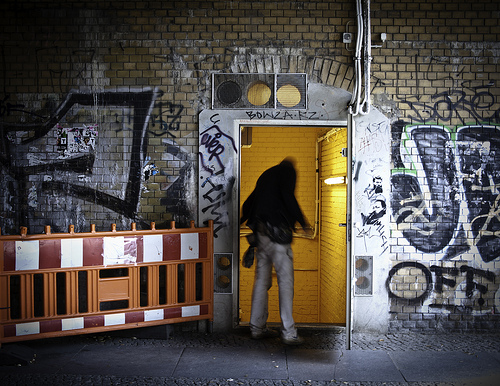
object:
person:
[241, 156, 318, 346]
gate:
[0, 218, 215, 353]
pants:
[252, 223, 300, 341]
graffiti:
[383, 260, 495, 313]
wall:
[2, 1, 499, 332]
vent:
[277, 72, 307, 112]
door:
[238, 124, 348, 327]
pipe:
[364, 0, 374, 111]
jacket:
[241, 163, 306, 234]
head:
[275, 156, 297, 178]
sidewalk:
[0, 332, 500, 386]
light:
[341, 31, 352, 44]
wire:
[353, 1, 361, 116]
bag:
[241, 232, 257, 267]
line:
[386, 350, 411, 384]